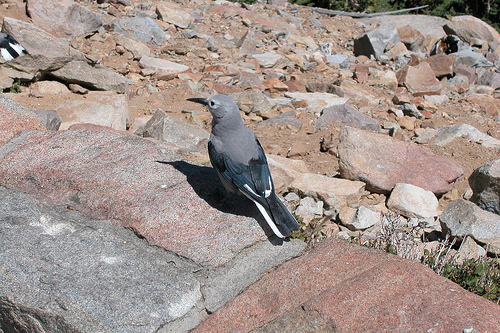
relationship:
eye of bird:
[211, 101, 215, 106] [185, 94, 301, 239]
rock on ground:
[113, 11, 172, 47] [1, 1, 499, 329]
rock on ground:
[2, 15, 93, 73] [1, 1, 499, 329]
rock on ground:
[335, 123, 472, 193] [244, 15, 476, 316]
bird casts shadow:
[185, 94, 301, 239] [152, 158, 291, 244]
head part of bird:
[206, 92, 238, 123] [185, 94, 301, 239]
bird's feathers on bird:
[252, 191, 301, 239] [185, 94, 301, 239]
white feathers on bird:
[247, 187, 287, 244] [182, 87, 278, 214]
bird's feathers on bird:
[252, 191, 301, 239] [182, 92, 304, 250]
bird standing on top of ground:
[175, 87, 313, 247] [1, 1, 499, 329]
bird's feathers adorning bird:
[252, 191, 301, 239] [185, 94, 301, 239]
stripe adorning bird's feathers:
[242, 182, 264, 199] [252, 191, 301, 239]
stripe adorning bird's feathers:
[262, 173, 272, 196] [252, 191, 301, 239]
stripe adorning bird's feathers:
[237, 188, 287, 240] [252, 191, 301, 239]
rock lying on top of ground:
[335, 123, 472, 193] [1, 1, 499, 329]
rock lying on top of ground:
[397, 62, 442, 94] [1, 1, 499, 329]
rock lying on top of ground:
[137, 54, 192, 79] [1, 1, 499, 329]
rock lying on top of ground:
[353, 29, 388, 57] [1, 1, 499, 329]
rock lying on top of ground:
[251, 50, 283, 66] [1, 1, 499, 329]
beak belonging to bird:
[181, 89, 207, 107] [175, 87, 313, 247]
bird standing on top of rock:
[185, 94, 301, 239] [1, 122, 308, 313]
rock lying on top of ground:
[384, 181, 442, 220] [1, 1, 499, 329]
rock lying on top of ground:
[140, 107, 212, 151] [1, 1, 499, 329]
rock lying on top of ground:
[360, 12, 401, 59] [1, 1, 499, 329]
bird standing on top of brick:
[185, 94, 301, 239] [2, 121, 309, 311]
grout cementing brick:
[158, 237, 303, 330] [192, 240, 497, 332]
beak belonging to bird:
[185, 97, 206, 106] [185, 94, 301, 239]